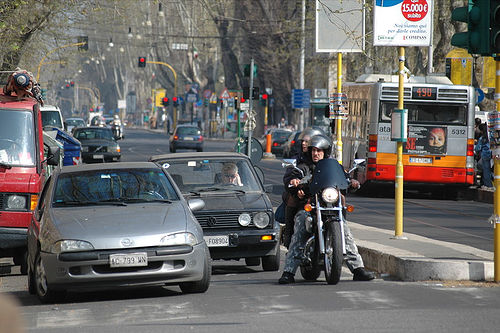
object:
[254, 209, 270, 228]
headlight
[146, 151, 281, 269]
car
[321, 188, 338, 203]
circle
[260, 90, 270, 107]
light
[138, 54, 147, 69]
light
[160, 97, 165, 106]
light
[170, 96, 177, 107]
light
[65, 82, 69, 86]
light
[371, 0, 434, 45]
sign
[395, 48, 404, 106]
pole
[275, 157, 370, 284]
motorcycle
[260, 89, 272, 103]
traffic light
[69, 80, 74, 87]
traffic light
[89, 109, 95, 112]
traffic light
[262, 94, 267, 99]
circle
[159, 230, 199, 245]
headlight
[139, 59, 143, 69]
light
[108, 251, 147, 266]
license plate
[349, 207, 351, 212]
light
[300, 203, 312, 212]
light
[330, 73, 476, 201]
bus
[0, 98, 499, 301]
traffic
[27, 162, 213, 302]
car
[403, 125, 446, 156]
sign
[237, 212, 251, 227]
headlight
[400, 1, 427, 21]
red circle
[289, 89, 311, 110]
sign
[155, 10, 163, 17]
light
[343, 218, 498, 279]
cement median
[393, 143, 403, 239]
yellow pole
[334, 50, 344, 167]
yellow pole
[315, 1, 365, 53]
sign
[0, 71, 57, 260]
truck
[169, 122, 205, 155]
car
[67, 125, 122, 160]
car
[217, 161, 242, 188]
person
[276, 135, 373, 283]
man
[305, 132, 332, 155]
helmet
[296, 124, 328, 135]
helmet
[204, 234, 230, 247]
plate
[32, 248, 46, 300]
tire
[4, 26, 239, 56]
wire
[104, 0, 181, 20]
wire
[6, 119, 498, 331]
roadway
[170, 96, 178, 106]
stop light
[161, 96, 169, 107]
stop light